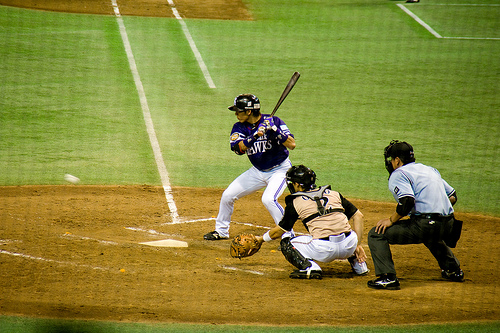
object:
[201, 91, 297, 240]
man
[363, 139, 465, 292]
man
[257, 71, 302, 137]
bat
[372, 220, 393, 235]
hand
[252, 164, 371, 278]
catcher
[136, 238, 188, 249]
plate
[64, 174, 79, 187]
ball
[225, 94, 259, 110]
helmet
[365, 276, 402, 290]
shoe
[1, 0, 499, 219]
grass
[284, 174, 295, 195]
mask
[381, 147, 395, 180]
mask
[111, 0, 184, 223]
line